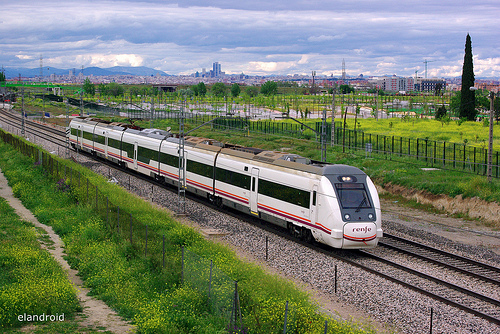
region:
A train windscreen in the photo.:
[339, 189, 371, 209]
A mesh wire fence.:
[132, 224, 178, 269]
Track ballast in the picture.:
[346, 277, 401, 309]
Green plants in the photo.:
[96, 239, 138, 290]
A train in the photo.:
[257, 167, 382, 247]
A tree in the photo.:
[459, 30, 476, 118]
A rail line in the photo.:
[413, 242, 490, 308]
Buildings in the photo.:
[365, 73, 442, 94]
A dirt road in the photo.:
[86, 302, 115, 330]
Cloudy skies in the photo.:
[143, 3, 375, 55]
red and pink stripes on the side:
[264, 203, 311, 221]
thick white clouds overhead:
[84, 11, 239, 63]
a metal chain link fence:
[107, 208, 159, 250]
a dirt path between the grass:
[11, 190, 31, 221]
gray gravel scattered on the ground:
[358, 265, 384, 312]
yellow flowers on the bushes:
[139, 300, 173, 326]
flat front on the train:
[329, 167, 384, 230]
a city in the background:
[118, 58, 423, 85]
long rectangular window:
[261, 176, 311, 206]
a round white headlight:
[341, 208, 356, 220]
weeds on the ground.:
[26, 277, 61, 300]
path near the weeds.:
[77, 288, 122, 321]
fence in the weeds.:
[140, 228, 189, 279]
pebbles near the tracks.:
[293, 250, 318, 273]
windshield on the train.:
[344, 190, 361, 202]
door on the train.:
[244, 170, 257, 218]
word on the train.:
[347, 223, 374, 235]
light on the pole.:
[472, 83, 484, 95]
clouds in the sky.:
[237, 23, 299, 35]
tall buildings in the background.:
[208, 57, 227, 76]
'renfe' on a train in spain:
[347, 223, 374, 234]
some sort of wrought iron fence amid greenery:
[0, 129, 335, 332]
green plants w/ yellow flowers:
[0, 208, 373, 331]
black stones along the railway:
[112, 173, 498, 330]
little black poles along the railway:
[40, 130, 444, 331]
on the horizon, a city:
[1, 59, 498, 94]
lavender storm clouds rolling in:
[1, 0, 498, 80]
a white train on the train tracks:
[67, 110, 382, 262]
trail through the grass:
[0, 169, 138, 331]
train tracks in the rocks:
[3, 100, 496, 325]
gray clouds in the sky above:
[10, 5, 499, 74]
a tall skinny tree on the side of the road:
[453, 28, 481, 121]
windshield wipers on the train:
[350, 191, 376, 218]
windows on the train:
[72, 124, 312, 212]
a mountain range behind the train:
[1, 60, 173, 82]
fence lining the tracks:
[5, 127, 320, 332]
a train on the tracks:
[33, 107, 420, 298]